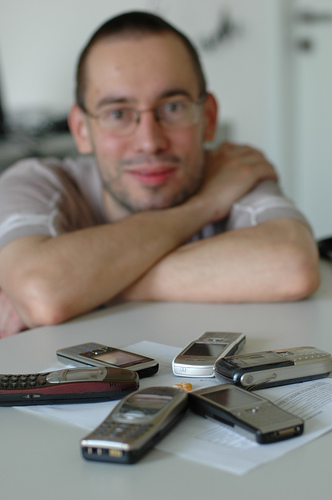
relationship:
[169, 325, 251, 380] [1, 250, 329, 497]
cellphone on table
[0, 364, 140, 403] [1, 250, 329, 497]
handset on table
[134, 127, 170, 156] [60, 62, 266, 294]
nose on man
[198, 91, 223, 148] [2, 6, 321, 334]
ear on man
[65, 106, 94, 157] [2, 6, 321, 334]
ear on man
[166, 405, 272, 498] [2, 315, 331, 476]
paper under phones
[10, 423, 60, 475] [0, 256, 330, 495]
table under phones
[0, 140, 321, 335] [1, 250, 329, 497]
arms are under table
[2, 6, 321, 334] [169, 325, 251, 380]
man has cellphone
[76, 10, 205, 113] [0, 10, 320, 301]
hair on man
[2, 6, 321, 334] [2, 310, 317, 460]
man looking camera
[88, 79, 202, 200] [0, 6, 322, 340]
face of man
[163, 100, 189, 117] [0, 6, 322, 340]
eye of man